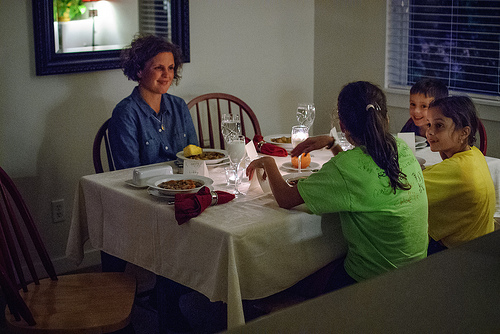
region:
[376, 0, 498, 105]
Window has white mini blind.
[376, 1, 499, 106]
It appears to be dark outside.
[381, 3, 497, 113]
Mini blind slats are open.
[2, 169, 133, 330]
Chair is pulled away from table.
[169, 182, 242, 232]
Cloth napkin is red.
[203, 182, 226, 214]
Napkin ring on napkin.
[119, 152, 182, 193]
White butter dish on table.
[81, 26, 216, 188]
Girl sitting at table.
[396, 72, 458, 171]
Boy is sitting at table.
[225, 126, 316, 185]
Two glass contain milk.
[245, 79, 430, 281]
Oldest girl wearing green shirt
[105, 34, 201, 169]
Smiling woman wearing blue shirt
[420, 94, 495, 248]
Younger girl wearing yellow shirt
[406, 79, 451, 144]
smiling boy looking at sister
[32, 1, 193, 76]
Mirror on wall framed in black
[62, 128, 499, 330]
Table has white tablecloth and red napkins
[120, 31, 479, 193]
Everyone has brown hair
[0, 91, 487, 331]
Wooden chairs are brown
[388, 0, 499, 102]
It is very dark and black outside the window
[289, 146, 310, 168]
the candle on the table is orange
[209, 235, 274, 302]
edge of white table cloth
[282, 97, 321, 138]
white drinking glass on table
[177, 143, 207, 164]
yellow cornbread on plate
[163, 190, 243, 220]
red napkin on table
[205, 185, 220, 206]
silver holder of red napkin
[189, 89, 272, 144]
circular wooden back of chair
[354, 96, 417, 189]
long black girl's ponytail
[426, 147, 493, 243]
girl wearing yellow shirt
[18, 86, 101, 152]
white wall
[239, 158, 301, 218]
girl's hand resting on table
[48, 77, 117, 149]
shadow is cast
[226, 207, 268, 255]
the table cloth white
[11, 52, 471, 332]
the chair is made of wood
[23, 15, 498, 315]
people are eating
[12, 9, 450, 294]
the room is well lit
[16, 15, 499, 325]
it is a dining room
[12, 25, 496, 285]
it is an indoor scene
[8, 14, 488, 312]
it is a nighttime scene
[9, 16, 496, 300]
the lights are on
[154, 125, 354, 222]
the plates are white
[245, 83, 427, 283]
girl wearing a tshirt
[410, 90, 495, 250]
young girl wearing a tshirt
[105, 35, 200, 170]
woman with curly short hair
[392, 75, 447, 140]
young boy sitting at table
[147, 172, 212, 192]
bowl filled with food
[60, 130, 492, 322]
white table cloth covering table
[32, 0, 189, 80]
black framed mirror on wall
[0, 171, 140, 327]
brown wooden chair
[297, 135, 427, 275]
bright green tshirt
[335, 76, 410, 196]
long brown hair in pony tail